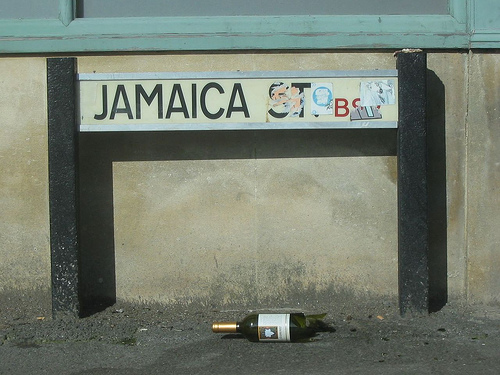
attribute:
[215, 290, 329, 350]
bottle —  glass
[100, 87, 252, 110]
writing —  black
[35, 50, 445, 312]
street board —  for street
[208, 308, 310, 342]
bottle — broken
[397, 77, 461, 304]
pillar — black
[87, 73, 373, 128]
board — for street,  written in black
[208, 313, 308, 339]
bottle — broken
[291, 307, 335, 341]
glass shard — broken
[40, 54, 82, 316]
post — black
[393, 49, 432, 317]
pole —  black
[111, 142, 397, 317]
grey wall — plain,  grey,  slab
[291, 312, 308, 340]
bottom —  green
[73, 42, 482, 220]
sign —   white,  Jamaica St.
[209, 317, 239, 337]
cap — golden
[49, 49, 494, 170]
board —  for street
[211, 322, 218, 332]
lid —  brown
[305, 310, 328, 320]
piece — broken, sharp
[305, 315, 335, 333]
piece — broken, sharp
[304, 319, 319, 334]
piece — broken, sharp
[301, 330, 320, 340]
piece — broken, sharp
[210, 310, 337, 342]
bottle — green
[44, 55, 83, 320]
post — black, thick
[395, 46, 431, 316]
post — black, thick